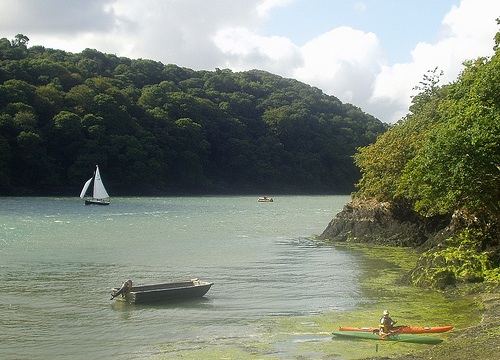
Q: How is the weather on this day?
A: It is cloudy.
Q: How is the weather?
A: It is cloudy.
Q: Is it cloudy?
A: Yes, it is cloudy.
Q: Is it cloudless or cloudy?
A: It is cloudy.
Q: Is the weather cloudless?
A: No, it is cloudy.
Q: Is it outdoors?
A: Yes, it is outdoors.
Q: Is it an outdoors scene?
A: Yes, it is outdoors.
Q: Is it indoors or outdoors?
A: It is outdoors.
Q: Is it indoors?
A: No, it is outdoors.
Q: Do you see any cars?
A: No, there are no cars.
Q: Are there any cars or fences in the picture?
A: No, there are no cars or fences.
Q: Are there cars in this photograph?
A: No, there are no cars.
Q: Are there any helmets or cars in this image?
A: No, there are no cars or helmets.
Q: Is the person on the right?
A: Yes, the person is on the right of the image.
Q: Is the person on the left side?
A: No, the person is on the right of the image.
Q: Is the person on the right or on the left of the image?
A: The person is on the right of the image.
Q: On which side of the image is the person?
A: The person is on the right of the image.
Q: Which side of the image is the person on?
A: The person is on the right of the image.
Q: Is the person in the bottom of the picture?
A: Yes, the person is in the bottom of the image.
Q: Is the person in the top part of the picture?
A: No, the person is in the bottom of the image.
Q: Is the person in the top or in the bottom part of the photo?
A: The person is in the bottom of the image.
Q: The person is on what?
A: The person is on the canoe.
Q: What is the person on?
A: The person is on the canoe.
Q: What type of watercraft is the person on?
A: The person is on the canoe.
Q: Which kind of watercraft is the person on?
A: The person is on the canoe.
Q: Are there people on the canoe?
A: Yes, there is a person on the canoe.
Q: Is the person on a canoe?
A: Yes, the person is on a canoe.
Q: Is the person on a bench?
A: No, the person is on a canoe.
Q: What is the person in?
A: The person is in the canoe.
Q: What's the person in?
A: The person is in the canoe.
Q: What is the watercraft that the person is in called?
A: The watercraft is a canoe.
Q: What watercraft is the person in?
A: The person is in the kayak.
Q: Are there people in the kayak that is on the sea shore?
A: Yes, there is a person in the canoe.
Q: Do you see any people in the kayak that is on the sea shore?
A: Yes, there is a person in the canoe.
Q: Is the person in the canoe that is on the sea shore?
A: Yes, the person is in the canoe.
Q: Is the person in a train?
A: No, the person is in the canoe.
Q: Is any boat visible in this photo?
A: Yes, there is a boat.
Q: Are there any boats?
A: Yes, there is a boat.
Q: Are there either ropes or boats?
A: Yes, there is a boat.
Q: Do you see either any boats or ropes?
A: Yes, there is a boat.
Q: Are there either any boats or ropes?
A: Yes, there is a boat.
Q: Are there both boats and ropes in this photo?
A: No, there is a boat but no ropes.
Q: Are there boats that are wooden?
A: Yes, there is a wood boat.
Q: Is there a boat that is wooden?
A: Yes, there is a boat that is wooden.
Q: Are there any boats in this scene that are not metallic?
A: Yes, there is a wooden boat.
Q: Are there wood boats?
A: Yes, there is a boat that is made of wood.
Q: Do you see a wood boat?
A: Yes, there is a boat that is made of wood.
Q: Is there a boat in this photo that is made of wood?
A: Yes, there is a boat that is made of wood.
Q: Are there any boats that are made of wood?
A: Yes, there is a boat that is made of wood.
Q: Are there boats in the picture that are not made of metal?
A: Yes, there is a boat that is made of wood.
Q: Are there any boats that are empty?
A: Yes, there is an empty boat.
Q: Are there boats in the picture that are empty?
A: Yes, there is a boat that is empty.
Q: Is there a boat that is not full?
A: Yes, there is a empty boat.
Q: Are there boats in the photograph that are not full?
A: Yes, there is a empty boat.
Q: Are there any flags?
A: No, there are no flags.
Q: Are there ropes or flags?
A: No, there are no flags or ropes.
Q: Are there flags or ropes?
A: No, there are no flags or ropes.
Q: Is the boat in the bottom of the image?
A: Yes, the boat is in the bottom of the image.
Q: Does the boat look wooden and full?
A: No, the boat is wooden but empty.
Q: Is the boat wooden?
A: Yes, the boat is wooden.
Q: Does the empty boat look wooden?
A: Yes, the boat is wooden.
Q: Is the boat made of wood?
A: Yes, the boat is made of wood.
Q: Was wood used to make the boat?
A: Yes, the boat is made of wood.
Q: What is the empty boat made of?
A: The boat is made of wood.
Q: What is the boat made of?
A: The boat is made of wood.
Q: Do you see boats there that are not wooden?
A: No, there is a boat but it is wooden.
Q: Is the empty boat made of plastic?
A: No, the boat is made of wood.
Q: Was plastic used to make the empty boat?
A: No, the boat is made of wood.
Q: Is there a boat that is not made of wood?
A: No, there is a boat but it is made of wood.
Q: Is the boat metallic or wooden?
A: The boat is wooden.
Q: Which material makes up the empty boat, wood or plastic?
A: The boat is made of wood.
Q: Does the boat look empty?
A: Yes, the boat is empty.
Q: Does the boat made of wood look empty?
A: Yes, the boat is empty.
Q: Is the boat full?
A: No, the boat is empty.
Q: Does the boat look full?
A: No, the boat is empty.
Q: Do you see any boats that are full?
A: No, there is a boat but it is empty.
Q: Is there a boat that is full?
A: No, there is a boat but it is empty.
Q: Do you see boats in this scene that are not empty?
A: No, there is a boat but it is empty.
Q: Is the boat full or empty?
A: The boat is empty.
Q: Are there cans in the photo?
A: No, there are no cans.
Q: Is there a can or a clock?
A: No, there are no cans or clocks.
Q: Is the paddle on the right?
A: Yes, the paddle is on the right of the image.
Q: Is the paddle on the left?
A: No, the paddle is on the right of the image.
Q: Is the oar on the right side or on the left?
A: The oar is on the right of the image.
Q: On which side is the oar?
A: The oar is on the right of the image.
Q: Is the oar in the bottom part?
A: Yes, the oar is in the bottom of the image.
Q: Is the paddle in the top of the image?
A: No, the paddle is in the bottom of the image.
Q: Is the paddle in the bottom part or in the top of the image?
A: The paddle is in the bottom of the image.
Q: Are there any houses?
A: No, there are no houses.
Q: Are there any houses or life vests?
A: No, there are no houses or life vests.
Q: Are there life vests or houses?
A: No, there are no houses or life vests.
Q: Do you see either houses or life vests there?
A: No, there are no houses or life vests.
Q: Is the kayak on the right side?
A: Yes, the kayak is on the right of the image.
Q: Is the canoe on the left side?
A: No, the canoe is on the right of the image.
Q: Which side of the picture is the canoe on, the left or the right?
A: The canoe is on the right of the image.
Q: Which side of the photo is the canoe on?
A: The canoe is on the right of the image.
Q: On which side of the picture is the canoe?
A: The canoe is on the right of the image.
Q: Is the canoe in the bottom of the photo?
A: Yes, the canoe is in the bottom of the image.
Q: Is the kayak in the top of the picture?
A: No, the kayak is in the bottom of the image.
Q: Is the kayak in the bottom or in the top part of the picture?
A: The kayak is in the bottom of the image.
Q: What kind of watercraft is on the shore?
A: The watercraft is a canoe.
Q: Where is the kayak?
A: The kayak is on the sea shore.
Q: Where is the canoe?
A: The kayak is on the sea shore.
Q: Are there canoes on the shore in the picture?
A: Yes, there is a canoe on the shore.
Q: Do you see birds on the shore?
A: No, there is a canoe on the shore.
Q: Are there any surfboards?
A: No, there are no surfboards.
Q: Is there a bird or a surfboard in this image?
A: No, there are no surfboards or birds.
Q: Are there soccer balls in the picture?
A: No, there are no soccer balls.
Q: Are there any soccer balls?
A: No, there are no soccer balls.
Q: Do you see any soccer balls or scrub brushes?
A: No, there are no soccer balls or scrub brushes.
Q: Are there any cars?
A: No, there are no cars.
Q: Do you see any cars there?
A: No, there are no cars.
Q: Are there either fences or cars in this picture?
A: No, there are no cars or fences.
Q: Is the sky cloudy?
A: Yes, the sky is cloudy.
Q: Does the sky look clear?
A: No, the sky is cloudy.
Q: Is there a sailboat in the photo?
A: Yes, there is a sailboat.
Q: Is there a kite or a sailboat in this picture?
A: Yes, there is a sailboat.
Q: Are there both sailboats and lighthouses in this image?
A: No, there is a sailboat but no lighthouses.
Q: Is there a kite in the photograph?
A: No, there are no kites.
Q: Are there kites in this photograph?
A: No, there are no kites.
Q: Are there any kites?
A: No, there are no kites.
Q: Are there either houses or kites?
A: No, there are no kites or houses.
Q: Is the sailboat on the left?
A: Yes, the sailboat is on the left of the image.